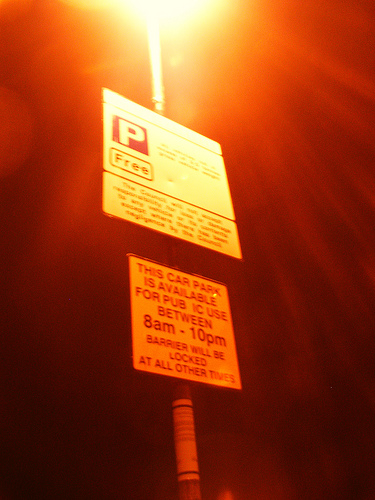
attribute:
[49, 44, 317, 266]
square — red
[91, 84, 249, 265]
sign — white, large, square, parking, car park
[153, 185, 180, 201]
line — red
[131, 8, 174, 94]
pole — long, thin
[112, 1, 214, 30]
light — orange, overhanging, bright